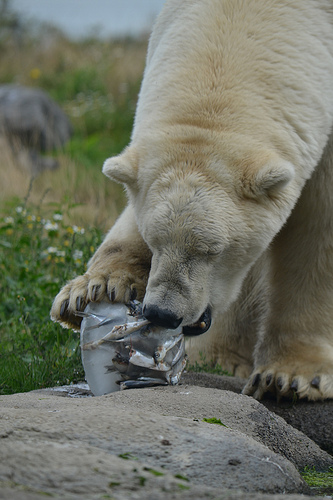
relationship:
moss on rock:
[187, 412, 226, 430] [13, 316, 296, 494]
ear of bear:
[98, 159, 138, 189] [54, 9, 332, 322]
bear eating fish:
[46, 0, 332, 405] [82, 297, 184, 389]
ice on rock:
[74, 287, 193, 404] [1, 364, 330, 499]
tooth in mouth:
[194, 318, 211, 334] [176, 298, 219, 342]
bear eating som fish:
[43, 48, 327, 337] [84, 288, 210, 401]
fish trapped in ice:
[82, 297, 184, 389] [80, 308, 181, 385]